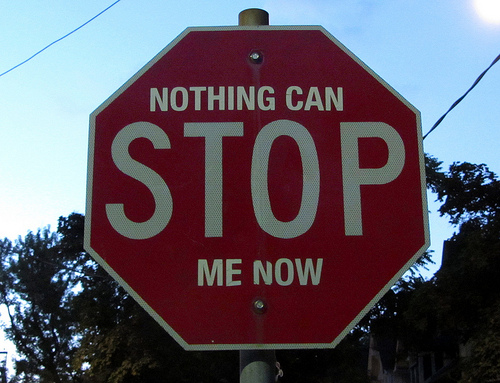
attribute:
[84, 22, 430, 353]
sign — red, white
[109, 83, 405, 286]
lettering — white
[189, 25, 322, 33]
edge — white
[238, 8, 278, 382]
pole — metal, silver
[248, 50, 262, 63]
bolt — silver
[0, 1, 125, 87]
power line — black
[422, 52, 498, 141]
power line — black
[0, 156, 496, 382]
trees — green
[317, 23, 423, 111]
edge — white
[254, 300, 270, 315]
bolt — silver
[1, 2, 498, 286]
sky — blue, clear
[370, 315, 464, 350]
roof — black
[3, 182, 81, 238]
clouds — white